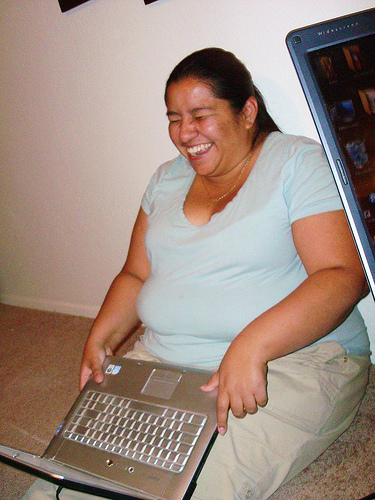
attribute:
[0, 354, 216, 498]
laptop — silver, gray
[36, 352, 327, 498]
lap — her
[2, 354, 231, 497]
computer — silver, personal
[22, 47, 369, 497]
woman — smiling, laughing, little overweight, brown, fat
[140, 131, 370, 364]
shirt — light, blue, light blue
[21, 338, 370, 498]
pants — khaki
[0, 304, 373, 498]
floor — beige, carpeted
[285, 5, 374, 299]
laptop — light, blue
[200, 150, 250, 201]
necklace — gold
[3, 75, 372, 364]
walls — painted, white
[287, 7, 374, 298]
phone — camera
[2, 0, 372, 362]
wall — creamy white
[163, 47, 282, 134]
hair — dark colored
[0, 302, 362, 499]
carpet — tan colored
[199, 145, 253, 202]
necklace — gold